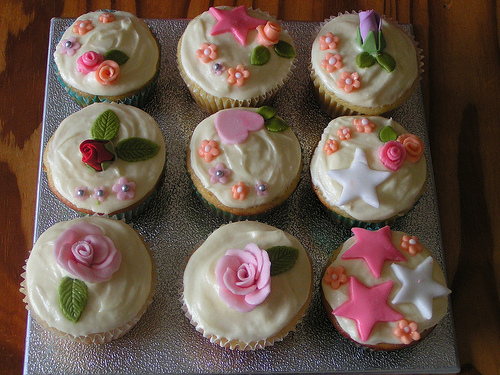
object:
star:
[341, 226, 408, 277]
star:
[327, 147, 394, 207]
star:
[210, 5, 270, 44]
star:
[391, 255, 452, 319]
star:
[333, 275, 403, 342]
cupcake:
[311, 117, 427, 228]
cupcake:
[322, 226, 452, 350]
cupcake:
[176, 7, 297, 113]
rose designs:
[54, 222, 122, 282]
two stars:
[333, 225, 407, 340]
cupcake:
[189, 108, 300, 217]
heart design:
[214, 109, 264, 144]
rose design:
[79, 138, 117, 172]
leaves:
[117, 136, 162, 162]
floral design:
[337, 72, 360, 92]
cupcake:
[309, 14, 423, 119]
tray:
[24, 17, 462, 374]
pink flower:
[60, 36, 80, 56]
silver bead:
[65, 41, 72, 48]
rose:
[58, 226, 120, 281]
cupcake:
[54, 11, 159, 108]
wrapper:
[53, 9, 162, 112]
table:
[0, 0, 499, 374]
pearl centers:
[328, 58, 335, 65]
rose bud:
[357, 9, 387, 54]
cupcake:
[43, 100, 169, 224]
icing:
[49, 102, 166, 212]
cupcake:
[20, 210, 157, 344]